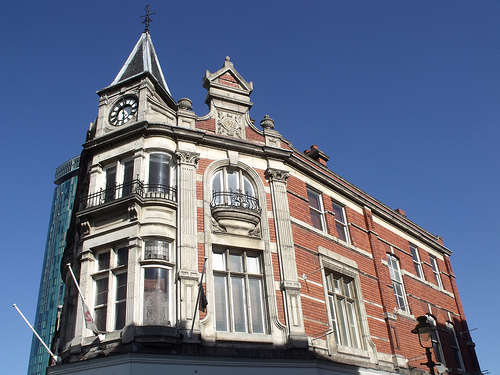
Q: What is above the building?
A: The clear sky.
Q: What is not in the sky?
A: Clouds.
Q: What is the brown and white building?
A: Multiple apartments.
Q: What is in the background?
A: A tall glass building.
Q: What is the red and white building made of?
A: Brick.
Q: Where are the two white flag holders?
A: In front of building.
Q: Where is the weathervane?
A: Top of building.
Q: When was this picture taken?
A: Daytime.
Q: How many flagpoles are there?
A: 3.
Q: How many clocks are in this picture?
A: 1.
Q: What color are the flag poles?
A: White.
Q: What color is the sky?
A: Blue.